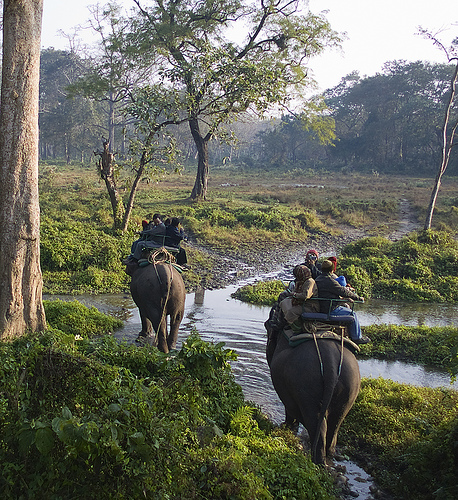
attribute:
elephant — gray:
[258, 293, 361, 474]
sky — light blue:
[41, 2, 457, 115]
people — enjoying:
[107, 199, 376, 357]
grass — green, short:
[0, 145, 287, 498]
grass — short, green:
[208, 193, 303, 237]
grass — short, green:
[149, 419, 237, 490]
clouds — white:
[44, 2, 456, 116]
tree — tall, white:
[102, 0, 327, 205]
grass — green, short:
[192, 357, 283, 434]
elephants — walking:
[258, 309, 371, 462]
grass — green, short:
[345, 381, 454, 491]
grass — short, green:
[69, 426, 196, 475]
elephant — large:
[131, 233, 186, 354]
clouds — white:
[2, 1, 457, 122]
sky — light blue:
[0, 0, 458, 121]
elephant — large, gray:
[263, 298, 359, 465]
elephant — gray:
[126, 259, 183, 351]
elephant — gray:
[127, 253, 184, 352]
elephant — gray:
[119, 255, 188, 355]